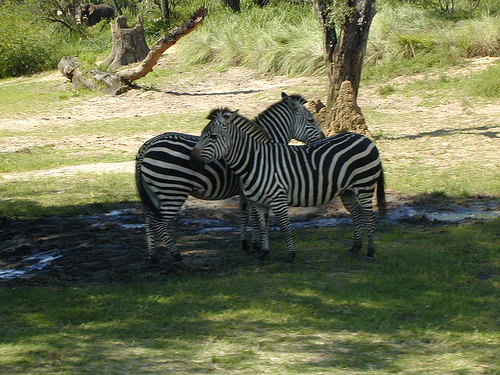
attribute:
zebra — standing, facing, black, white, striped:
[212, 109, 391, 257]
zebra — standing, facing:
[125, 82, 312, 248]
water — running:
[405, 204, 493, 219]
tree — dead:
[92, 11, 163, 72]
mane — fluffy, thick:
[229, 115, 273, 143]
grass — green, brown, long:
[212, 33, 321, 79]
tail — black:
[379, 144, 385, 214]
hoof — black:
[284, 252, 298, 262]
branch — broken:
[63, 44, 120, 93]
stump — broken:
[131, 29, 196, 79]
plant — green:
[10, 40, 53, 70]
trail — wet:
[210, 221, 390, 244]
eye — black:
[208, 133, 226, 145]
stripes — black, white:
[260, 153, 362, 179]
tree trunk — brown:
[323, 6, 370, 121]